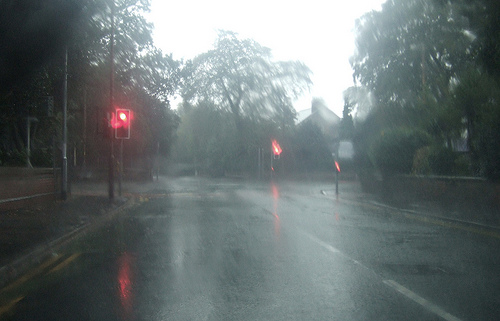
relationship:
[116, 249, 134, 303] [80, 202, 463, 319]
light on ground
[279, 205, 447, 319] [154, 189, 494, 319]
line painted on ground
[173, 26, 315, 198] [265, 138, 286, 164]
tree by street light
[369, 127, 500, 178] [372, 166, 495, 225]
bush behind barrier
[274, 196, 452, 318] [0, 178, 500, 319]
white line in center of ground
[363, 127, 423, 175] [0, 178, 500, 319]
bush on side of ground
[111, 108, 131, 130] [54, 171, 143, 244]
blurry/red light on corner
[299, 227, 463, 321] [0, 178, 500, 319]
line on ground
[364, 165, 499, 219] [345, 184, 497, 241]
stone wall next to sidewalk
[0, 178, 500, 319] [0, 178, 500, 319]
ground in ground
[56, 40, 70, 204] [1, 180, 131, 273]
large/gray pole on sidewalk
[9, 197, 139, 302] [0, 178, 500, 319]
curb on ground